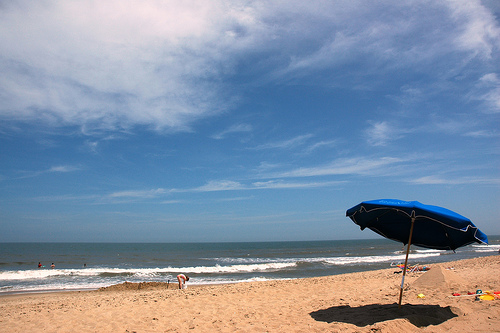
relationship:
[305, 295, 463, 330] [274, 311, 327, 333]
shadow on sand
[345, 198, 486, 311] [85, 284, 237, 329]
umbrella on beach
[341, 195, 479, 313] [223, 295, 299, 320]
umbrella on sand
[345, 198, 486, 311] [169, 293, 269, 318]
umbrella on sand